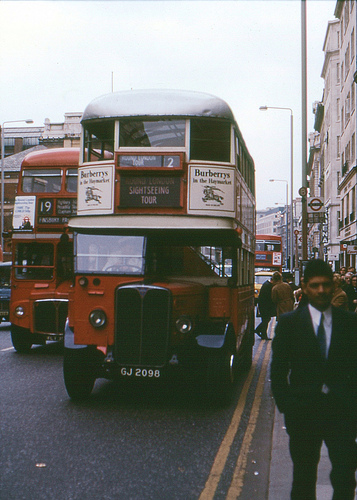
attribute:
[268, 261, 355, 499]
man — wearing tie, dark, walking, wearing suit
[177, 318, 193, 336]
headlight — on bus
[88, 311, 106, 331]
headlight — on bus, on the bus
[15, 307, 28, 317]
headlight — on bus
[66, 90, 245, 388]
bus — double decket, red, two decker, white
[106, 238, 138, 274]
driver — inside bus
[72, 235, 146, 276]
windshield — on bus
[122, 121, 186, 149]
window — on bus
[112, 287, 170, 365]
grill — on bus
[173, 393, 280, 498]
line — yellow, double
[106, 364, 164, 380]
tag — on front of bus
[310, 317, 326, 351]
shirt — black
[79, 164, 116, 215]
advertisement — on front of bus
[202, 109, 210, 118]
dent — in bus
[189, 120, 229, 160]
window — without glass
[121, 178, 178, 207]
sign — on bus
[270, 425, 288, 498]
pavement — grey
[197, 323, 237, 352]
fender — over wheel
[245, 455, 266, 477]
litter — on street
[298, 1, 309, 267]
pole — metal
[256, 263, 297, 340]
people — on street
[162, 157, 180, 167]
numeration — on bus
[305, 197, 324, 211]
sign — posted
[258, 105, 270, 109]
lamp — white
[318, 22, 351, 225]
building — commerical, tall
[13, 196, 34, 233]
advertising — on bus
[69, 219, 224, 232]
levels — on bus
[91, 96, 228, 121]
roof — shiny